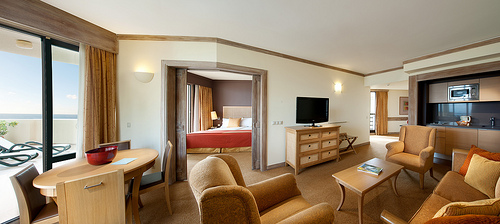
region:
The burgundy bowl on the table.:
[83, 143, 117, 164]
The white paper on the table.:
[110, 153, 137, 165]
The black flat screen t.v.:
[291, 95, 333, 125]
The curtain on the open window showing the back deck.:
[79, 45, 125, 152]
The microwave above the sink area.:
[445, 85, 483, 99]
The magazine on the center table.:
[359, 160, 382, 177]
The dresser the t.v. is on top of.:
[288, 126, 343, 163]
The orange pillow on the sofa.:
[458, 145, 498, 175]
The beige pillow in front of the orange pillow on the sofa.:
[470, 150, 496, 192]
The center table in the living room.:
[321, 150, 401, 207]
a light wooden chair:
[330, 154, 405, 222]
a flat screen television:
[293, 94, 333, 128]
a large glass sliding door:
[1, 15, 116, 222]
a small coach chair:
[384, 118, 437, 190]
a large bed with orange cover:
[186, 105, 258, 152]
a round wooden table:
[32, 143, 163, 221]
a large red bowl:
[83, 141, 118, 164]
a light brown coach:
[378, 141, 498, 223]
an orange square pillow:
[457, 139, 498, 175]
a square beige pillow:
[461, 148, 498, 198]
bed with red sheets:
[181, 103, 265, 156]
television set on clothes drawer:
[281, 85, 341, 177]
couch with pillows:
[375, 143, 499, 223]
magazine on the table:
[327, 153, 411, 222]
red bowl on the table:
[25, 138, 163, 221]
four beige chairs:
[7, 135, 176, 222]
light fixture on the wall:
[126, 53, 158, 95]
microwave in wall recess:
[441, 78, 482, 105]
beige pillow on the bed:
[184, 97, 254, 159]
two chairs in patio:
[0, 114, 84, 222]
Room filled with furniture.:
[187, 115, 496, 221]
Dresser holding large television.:
[285, 93, 345, 173]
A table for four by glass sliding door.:
[4, 138, 174, 220]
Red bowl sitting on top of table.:
[80, 135, 118, 167]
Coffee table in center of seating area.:
[326, 152, 408, 222]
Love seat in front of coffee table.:
[390, 141, 497, 222]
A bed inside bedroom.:
[188, 96, 254, 154]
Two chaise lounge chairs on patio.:
[1, 129, 76, 166]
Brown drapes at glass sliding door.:
[73, 41, 133, 167]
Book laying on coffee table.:
[353, 159, 388, 179]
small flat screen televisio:
[292, 95, 332, 126]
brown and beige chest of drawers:
[284, 122, 341, 172]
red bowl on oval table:
[82, 142, 120, 166]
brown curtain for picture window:
[81, 46, 120, 151]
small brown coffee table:
[329, 154, 408, 221]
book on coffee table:
[357, 162, 387, 174]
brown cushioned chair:
[383, 122, 438, 187]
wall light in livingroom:
[127, 65, 156, 88]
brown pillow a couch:
[461, 151, 498, 195]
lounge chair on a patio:
[0, 134, 72, 155]